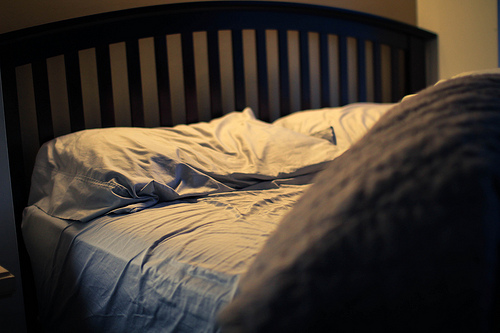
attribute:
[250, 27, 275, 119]
slat — dark 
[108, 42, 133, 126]
slat — dark 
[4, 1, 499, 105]
walls — White 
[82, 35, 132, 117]
slat — dark 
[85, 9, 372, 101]
headboard — dark brown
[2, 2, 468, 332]
bed — comfortable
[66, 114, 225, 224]
white pillows — ruffled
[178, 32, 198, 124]
slat — dark 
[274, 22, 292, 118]
slat — dark 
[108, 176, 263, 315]
sheets — White 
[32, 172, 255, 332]
sheet — wrinkly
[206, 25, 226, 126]
bar — wooden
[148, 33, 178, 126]
bar — wooden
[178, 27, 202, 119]
bar — wooden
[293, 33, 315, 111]
bar — wooden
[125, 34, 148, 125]
bar — wooden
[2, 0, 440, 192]
head board — wooden